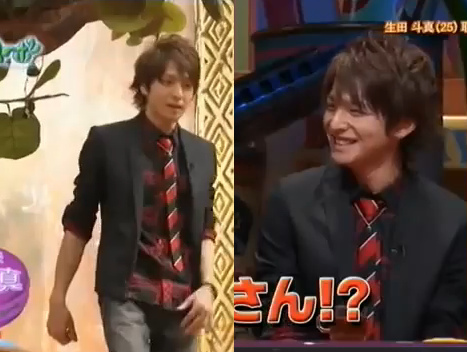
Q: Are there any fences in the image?
A: No, there are no fences.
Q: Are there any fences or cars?
A: No, there are no fences or cars.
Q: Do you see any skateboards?
A: No, there are no skateboards.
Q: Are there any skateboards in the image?
A: No, there are no skateboards.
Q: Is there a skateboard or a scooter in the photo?
A: No, there are no skateboards or scooters.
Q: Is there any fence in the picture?
A: No, there are no fences.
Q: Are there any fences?
A: No, there are no fences.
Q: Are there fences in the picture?
A: No, there are no fences.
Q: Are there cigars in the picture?
A: No, there are no cigars.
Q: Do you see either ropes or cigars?
A: No, there are no cigars or ropes.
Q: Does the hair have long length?
A: Yes, the hair is long.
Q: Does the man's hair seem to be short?
A: No, the hair is long.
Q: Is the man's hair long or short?
A: The hair is long.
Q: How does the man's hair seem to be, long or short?
A: The hair is long.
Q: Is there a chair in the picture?
A: No, there are no chairs.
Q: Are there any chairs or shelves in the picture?
A: No, there are no chairs or shelves.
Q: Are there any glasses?
A: No, there are no glasses.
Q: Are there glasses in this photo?
A: No, there are no glasses.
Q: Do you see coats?
A: Yes, there is a coat.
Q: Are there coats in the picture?
A: Yes, there is a coat.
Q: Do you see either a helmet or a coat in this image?
A: Yes, there is a coat.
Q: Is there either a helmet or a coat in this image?
A: Yes, there is a coat.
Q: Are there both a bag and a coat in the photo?
A: No, there is a coat but no bags.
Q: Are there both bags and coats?
A: No, there is a coat but no bags.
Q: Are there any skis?
A: No, there are no skis.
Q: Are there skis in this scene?
A: No, there are no skis.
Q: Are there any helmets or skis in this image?
A: No, there are no skis or helmets.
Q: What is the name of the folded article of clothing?
A: The clothing item is a coat.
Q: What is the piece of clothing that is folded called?
A: The clothing item is a coat.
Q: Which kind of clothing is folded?
A: The clothing is a coat.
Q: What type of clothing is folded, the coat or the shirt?
A: The coat is folded.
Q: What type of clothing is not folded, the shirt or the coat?
A: The shirt is not folded.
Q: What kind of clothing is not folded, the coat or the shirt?
A: The shirt is not folded.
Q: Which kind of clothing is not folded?
A: The clothing is a shirt.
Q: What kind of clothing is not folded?
A: The clothing is a shirt.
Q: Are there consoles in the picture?
A: No, there are no consoles.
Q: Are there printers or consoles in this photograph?
A: No, there are no consoles or printers.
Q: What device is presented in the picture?
A: The device is a screen.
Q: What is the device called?
A: The device is a screen.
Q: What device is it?
A: The device is a screen.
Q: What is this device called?
A: This is a screen.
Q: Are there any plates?
A: No, there are no plates.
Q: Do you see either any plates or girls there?
A: No, there are no plates or girls.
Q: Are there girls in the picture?
A: No, there are no girls.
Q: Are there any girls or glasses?
A: No, there are no girls or glasses.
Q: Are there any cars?
A: No, there are no cars.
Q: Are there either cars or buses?
A: No, there are no cars or buses.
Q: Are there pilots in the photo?
A: No, there are no pilots.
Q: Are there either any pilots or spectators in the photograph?
A: No, there are no pilots or spectators.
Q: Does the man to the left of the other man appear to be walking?
A: Yes, the man is walking.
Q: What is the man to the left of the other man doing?
A: The man is walking.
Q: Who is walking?
A: The man is walking.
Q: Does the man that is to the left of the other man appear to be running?
A: No, the man is walking.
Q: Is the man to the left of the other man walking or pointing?
A: The man is walking.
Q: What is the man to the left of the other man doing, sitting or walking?
A: The man is walking.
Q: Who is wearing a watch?
A: The man is wearing a watch.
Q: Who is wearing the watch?
A: The man is wearing a watch.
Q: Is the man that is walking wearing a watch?
A: Yes, the man is wearing a watch.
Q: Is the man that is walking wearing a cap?
A: No, the man is wearing a watch.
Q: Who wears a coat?
A: The man wears a coat.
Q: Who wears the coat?
A: The man wears a coat.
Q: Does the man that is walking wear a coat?
A: Yes, the man wears a coat.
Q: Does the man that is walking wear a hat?
A: No, the man wears a coat.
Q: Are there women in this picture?
A: No, there are no women.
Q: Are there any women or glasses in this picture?
A: No, there are no women or glasses.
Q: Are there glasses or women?
A: No, there are no women or glasses.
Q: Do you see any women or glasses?
A: No, there are no women or glasses.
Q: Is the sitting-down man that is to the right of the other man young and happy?
A: Yes, the man is young and happy.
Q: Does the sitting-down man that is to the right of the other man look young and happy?
A: Yes, the man is young and happy.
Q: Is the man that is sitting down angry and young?
A: No, the man is young but happy.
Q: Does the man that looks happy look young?
A: Yes, the man is young.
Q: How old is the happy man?
A: The man is young.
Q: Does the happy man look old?
A: No, the man is young.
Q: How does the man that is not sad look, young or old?
A: The man is young.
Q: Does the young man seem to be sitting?
A: Yes, the man is sitting.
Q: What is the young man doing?
A: The man is sitting.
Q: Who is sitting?
A: The man is sitting.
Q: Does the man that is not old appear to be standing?
A: No, the man is sitting.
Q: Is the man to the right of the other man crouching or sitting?
A: The man is sitting.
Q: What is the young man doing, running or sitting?
A: The man is sitting.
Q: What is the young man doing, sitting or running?
A: The man is sitting.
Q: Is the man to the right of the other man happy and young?
A: Yes, the man is happy and young.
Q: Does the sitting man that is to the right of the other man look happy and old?
A: No, the man is happy but young.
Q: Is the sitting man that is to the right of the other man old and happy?
A: No, the man is happy but young.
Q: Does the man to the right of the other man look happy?
A: Yes, the man is happy.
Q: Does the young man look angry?
A: No, the man is happy.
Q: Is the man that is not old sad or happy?
A: The man is happy.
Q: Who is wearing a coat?
A: The man is wearing a coat.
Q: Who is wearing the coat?
A: The man is wearing a coat.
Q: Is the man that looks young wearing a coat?
A: Yes, the man is wearing a coat.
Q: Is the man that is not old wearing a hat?
A: No, the man is wearing a coat.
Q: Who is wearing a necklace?
A: The man is wearing a necklace.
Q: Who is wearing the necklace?
A: The man is wearing a necklace.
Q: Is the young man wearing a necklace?
A: Yes, the man is wearing a necklace.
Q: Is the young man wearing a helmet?
A: No, the man is wearing a necklace.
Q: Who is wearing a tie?
A: The man is wearing a tie.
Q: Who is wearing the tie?
A: The man is wearing a tie.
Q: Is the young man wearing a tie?
A: Yes, the man is wearing a tie.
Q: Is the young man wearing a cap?
A: No, the man is wearing a tie.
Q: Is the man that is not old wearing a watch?
A: Yes, the man is wearing a watch.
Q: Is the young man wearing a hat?
A: No, the man is wearing a watch.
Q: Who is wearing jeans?
A: The man is wearing jeans.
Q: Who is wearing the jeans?
A: The man is wearing jeans.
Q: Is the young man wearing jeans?
A: Yes, the man is wearing jeans.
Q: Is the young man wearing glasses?
A: No, the man is wearing jeans.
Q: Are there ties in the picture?
A: Yes, there is a tie.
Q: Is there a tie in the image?
A: Yes, there is a tie.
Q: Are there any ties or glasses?
A: Yes, there is a tie.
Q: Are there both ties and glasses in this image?
A: No, there is a tie but no glasses.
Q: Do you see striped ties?
A: Yes, there is a striped tie.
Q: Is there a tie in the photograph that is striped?
A: Yes, there is a tie that is striped.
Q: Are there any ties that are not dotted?
A: Yes, there is a striped tie.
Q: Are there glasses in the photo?
A: No, there are no glasses.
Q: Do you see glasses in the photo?
A: No, there are no glasses.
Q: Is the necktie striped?
A: Yes, the necktie is striped.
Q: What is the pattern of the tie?
A: The necktie is striped.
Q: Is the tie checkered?
A: No, the tie is striped.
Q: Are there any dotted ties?
A: No, there is a tie but it is striped.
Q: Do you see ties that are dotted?
A: No, there is a tie but it is striped.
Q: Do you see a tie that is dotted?
A: No, there is a tie but it is striped.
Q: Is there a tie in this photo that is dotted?
A: No, there is a tie but it is striped.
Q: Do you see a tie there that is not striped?
A: No, there is a tie but it is striped.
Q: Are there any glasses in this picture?
A: No, there are no glasses.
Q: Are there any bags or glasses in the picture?
A: No, there are no glasses or bags.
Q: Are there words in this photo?
A: Yes, there are words.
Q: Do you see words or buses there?
A: Yes, there are words.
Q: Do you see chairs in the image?
A: No, there are no chairs.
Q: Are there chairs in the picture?
A: No, there are no chairs.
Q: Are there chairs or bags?
A: No, there are no chairs or bags.